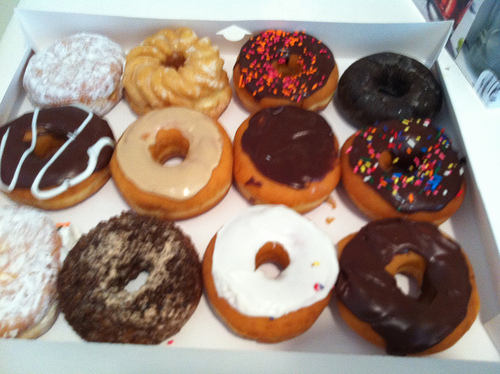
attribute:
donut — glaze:
[116, 24, 233, 122]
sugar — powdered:
[2, 215, 45, 306]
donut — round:
[328, 214, 495, 357]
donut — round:
[331, 49, 443, 125]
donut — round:
[340, 215, 484, 352]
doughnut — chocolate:
[465, 309, 477, 328]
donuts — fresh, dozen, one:
[4, 16, 484, 359]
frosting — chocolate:
[361, 226, 475, 335]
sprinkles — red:
[382, 154, 453, 181]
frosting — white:
[230, 214, 315, 304]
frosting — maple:
[134, 130, 221, 181]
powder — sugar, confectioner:
[39, 30, 119, 103]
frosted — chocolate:
[350, 227, 460, 329]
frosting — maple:
[132, 106, 208, 191]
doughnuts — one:
[25, 40, 455, 349]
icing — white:
[204, 209, 324, 335]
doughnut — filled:
[45, 38, 115, 104]